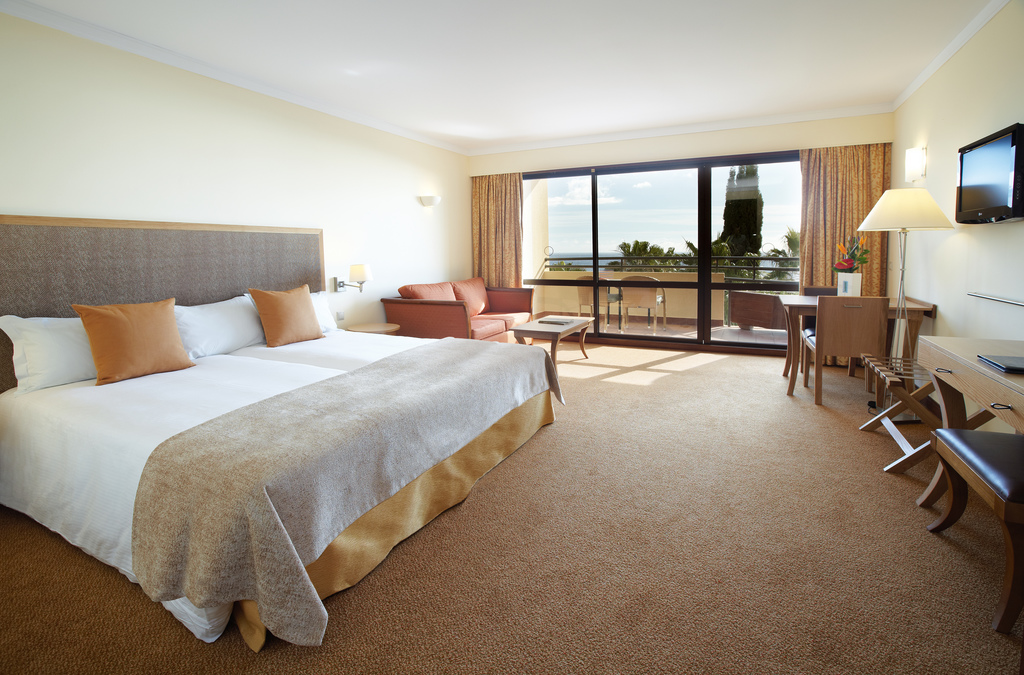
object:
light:
[323, 252, 377, 297]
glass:
[521, 173, 598, 284]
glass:
[595, 166, 697, 284]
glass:
[710, 160, 805, 285]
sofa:
[381, 277, 535, 345]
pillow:
[69, 297, 197, 386]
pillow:
[247, 284, 326, 349]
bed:
[0, 214, 569, 652]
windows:
[514, 159, 801, 351]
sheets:
[0, 286, 569, 654]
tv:
[953, 123, 1024, 225]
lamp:
[857, 187, 956, 318]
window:
[518, 172, 594, 335]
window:
[599, 169, 698, 345]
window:
[706, 153, 801, 351]